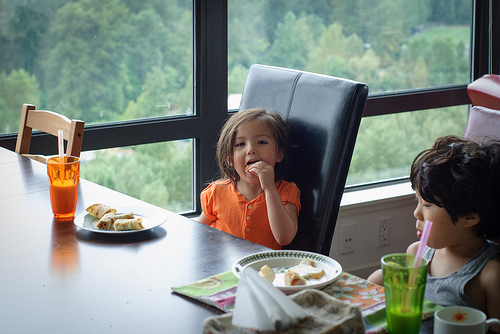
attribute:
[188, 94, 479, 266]
children — young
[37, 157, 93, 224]
glass — orange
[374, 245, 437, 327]
glass — green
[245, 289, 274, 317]
napkin — white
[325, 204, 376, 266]
outlet — white, wall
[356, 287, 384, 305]
flower — white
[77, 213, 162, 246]
plate — white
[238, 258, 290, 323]
tissue — sticking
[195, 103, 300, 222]
girl — eating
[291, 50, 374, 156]
chair — wooden, leather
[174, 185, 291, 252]
shirt — girl, orange, button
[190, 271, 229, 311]
mug — white, coffee, place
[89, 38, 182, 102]
window — part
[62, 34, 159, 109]
tree — green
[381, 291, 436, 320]
cup — green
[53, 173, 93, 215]
cup — orange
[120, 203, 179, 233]
dish — white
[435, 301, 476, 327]
cup — coffee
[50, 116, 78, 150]
straw — white